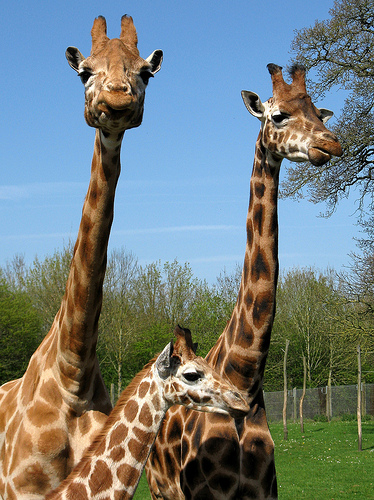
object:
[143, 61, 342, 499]
giraffe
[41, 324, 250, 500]
giraffe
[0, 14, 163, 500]
giraffe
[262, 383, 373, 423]
fence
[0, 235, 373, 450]
wooded area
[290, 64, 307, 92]
horn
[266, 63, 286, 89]
horn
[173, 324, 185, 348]
horn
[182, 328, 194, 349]
horn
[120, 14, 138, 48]
horn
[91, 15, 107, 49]
horn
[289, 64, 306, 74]
tip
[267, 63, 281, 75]
tip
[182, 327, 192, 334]
tip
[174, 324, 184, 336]
tip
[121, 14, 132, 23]
tip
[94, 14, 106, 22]
tip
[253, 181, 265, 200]
marking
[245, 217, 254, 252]
marking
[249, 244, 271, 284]
marking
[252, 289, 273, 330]
marking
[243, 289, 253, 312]
marking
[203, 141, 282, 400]
neck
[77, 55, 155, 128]
face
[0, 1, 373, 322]
sky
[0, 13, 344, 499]
trio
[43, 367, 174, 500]
neck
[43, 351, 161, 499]
mane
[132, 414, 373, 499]
grass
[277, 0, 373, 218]
tree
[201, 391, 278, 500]
front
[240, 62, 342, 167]
head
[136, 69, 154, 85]
left eye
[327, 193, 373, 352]
branches